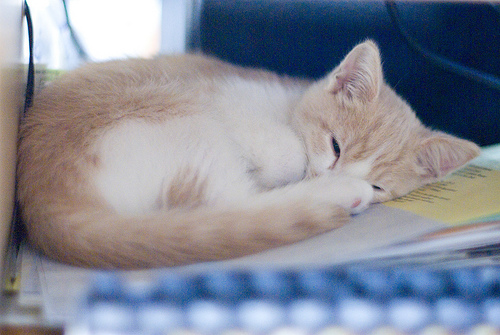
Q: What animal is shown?
A: Cat.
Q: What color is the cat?
A: Orange, white.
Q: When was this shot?
A: Daytime.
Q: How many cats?
A: 1.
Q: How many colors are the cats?
A: 2.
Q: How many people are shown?
A: 0.